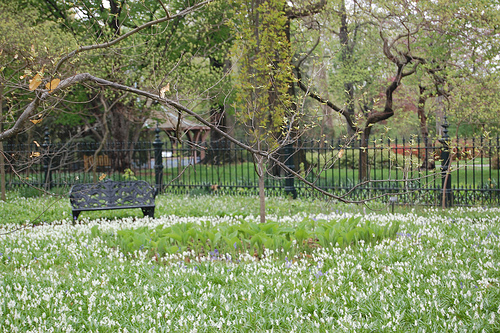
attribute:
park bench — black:
[62, 174, 174, 231]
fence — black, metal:
[2, 131, 485, 220]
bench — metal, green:
[63, 169, 174, 229]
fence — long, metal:
[9, 132, 483, 204]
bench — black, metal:
[62, 174, 164, 227]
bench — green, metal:
[66, 178, 156, 216]